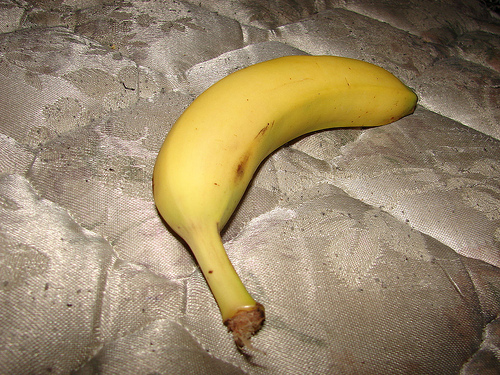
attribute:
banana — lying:
[141, 14, 418, 358]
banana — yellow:
[154, 165, 231, 250]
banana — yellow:
[128, 37, 432, 371]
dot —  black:
[230, 150, 251, 180]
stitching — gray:
[106, 312, 222, 371]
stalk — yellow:
[196, 243, 265, 343]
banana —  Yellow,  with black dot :
[99, 19, 461, 358]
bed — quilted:
[8, 2, 498, 367]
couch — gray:
[5, 2, 497, 374]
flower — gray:
[61, 1, 165, 72]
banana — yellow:
[114, 44, 330, 270]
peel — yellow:
[143, 68, 428, 320]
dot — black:
[232, 158, 253, 189]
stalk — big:
[191, 243, 266, 358]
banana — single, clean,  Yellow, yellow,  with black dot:
[152, 53, 417, 348]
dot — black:
[205, 267, 215, 274]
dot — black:
[211, 181, 221, 186]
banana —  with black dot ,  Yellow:
[107, 30, 449, 319]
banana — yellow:
[119, 41, 473, 276]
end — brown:
[208, 278, 285, 350]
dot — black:
[230, 148, 255, 191]